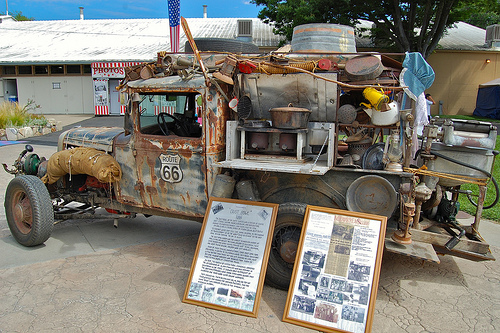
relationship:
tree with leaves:
[250, 0, 499, 60] [251, 0, 499, 50]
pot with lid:
[263, 100, 318, 140] [269, 100, 309, 117]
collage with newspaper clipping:
[287, 201, 387, 331] [323, 215, 352, 279]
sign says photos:
[89, 67, 136, 80] [93, 65, 122, 75]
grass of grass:
[439, 112, 500, 222] [439, 112, 495, 214]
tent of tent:
[469, 82, 499, 120] [469, 75, 499, 121]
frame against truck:
[178, 199, 280, 317] [7, 64, 496, 288]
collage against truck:
[281, 201, 387, 333] [7, 64, 496, 288]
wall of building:
[440, 59, 466, 91] [393, 27, 497, 119]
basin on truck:
[289, 21, 356, 60] [7, 64, 496, 288]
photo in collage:
[348, 257, 375, 290] [281, 201, 387, 333]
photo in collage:
[304, 246, 329, 273] [281, 201, 387, 333]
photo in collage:
[315, 296, 342, 325] [281, 201, 387, 333]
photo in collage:
[290, 293, 312, 316] [281, 201, 387, 333]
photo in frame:
[319, 276, 330, 287] [289, 193, 434, 328]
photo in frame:
[314, 286, 344, 306] [289, 193, 434, 328]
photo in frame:
[349, 258, 371, 280] [289, 193, 434, 328]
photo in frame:
[303, 248, 323, 269] [289, 193, 434, 328]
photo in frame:
[342, 304, 365, 323] [289, 193, 434, 328]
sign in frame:
[182, 196, 277, 318] [178, 190, 280, 317]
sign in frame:
[280, 203, 388, 333] [284, 200, 396, 330]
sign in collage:
[275, 195, 417, 331] [281, 201, 387, 333]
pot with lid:
[267, 101, 311, 130] [265, 103, 312, 118]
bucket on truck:
[343, 177, 404, 220] [28, 45, 498, 314]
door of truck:
[135, 86, 210, 225] [7, 64, 496, 288]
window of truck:
[123, 81, 191, 146] [7, 64, 496, 288]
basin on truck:
[289, 15, 379, 60] [7, 64, 496, 288]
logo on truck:
[159, 152, 183, 182] [7, 64, 496, 288]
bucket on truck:
[343, 176, 404, 220] [7, 64, 496, 288]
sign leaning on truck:
[182, 188, 277, 318] [1, 23, 484, 225]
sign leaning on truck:
[280, 203, 388, 333] [1, 23, 484, 225]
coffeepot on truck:
[361, 85, 391, 113] [1, 49, 498, 261]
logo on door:
[157, 151, 183, 183] [135, 86, 210, 225]